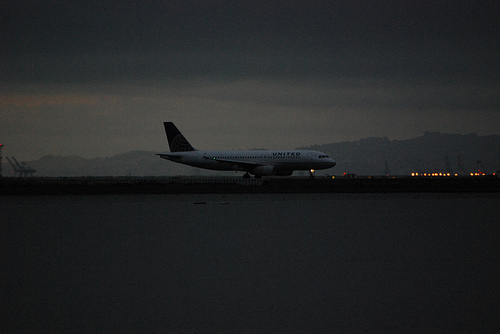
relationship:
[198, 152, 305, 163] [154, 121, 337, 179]
windows on airplane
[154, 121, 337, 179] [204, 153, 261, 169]
airplane has wing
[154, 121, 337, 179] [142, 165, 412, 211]
airplane on runway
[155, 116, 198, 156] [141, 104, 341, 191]
tail on top of airplane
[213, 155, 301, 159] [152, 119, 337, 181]
windows on side of airplane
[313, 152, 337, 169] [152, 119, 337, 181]
windshield on front of airplane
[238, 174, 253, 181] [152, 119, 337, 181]
wheels on bottom of airplane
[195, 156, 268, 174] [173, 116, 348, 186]
wing on side of airplane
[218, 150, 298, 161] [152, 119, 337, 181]
name on side of airplane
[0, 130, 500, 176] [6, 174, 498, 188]
hill bordering tarmac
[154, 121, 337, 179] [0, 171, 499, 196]
airplane on a runway